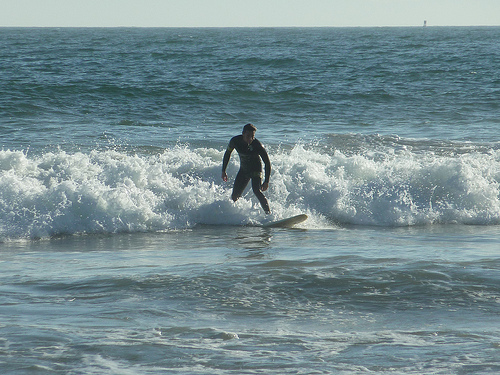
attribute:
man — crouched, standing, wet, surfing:
[218, 122, 278, 219]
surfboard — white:
[257, 212, 306, 231]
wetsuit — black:
[224, 135, 270, 213]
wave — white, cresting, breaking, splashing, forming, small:
[3, 141, 499, 237]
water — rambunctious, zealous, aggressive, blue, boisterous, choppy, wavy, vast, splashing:
[0, 21, 499, 374]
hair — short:
[239, 123, 256, 135]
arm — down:
[259, 140, 272, 192]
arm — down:
[221, 140, 235, 186]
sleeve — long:
[260, 140, 275, 175]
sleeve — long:
[221, 137, 234, 167]